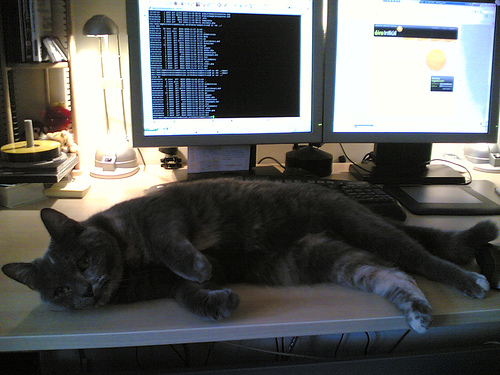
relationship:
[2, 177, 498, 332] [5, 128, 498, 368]
cat resting on desk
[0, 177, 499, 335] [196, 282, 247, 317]
cat has paws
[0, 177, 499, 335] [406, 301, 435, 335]
cat has foot